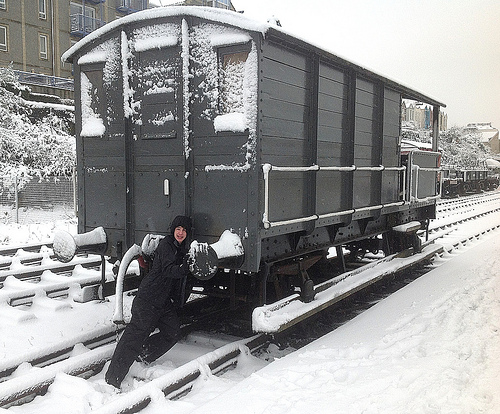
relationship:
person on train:
[81, 208, 202, 395] [65, 14, 441, 276]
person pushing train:
[81, 208, 202, 395] [65, 14, 441, 276]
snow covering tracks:
[21, 374, 97, 413] [9, 324, 229, 413]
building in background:
[1, 1, 147, 105] [1, 84, 78, 106]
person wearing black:
[81, 208, 202, 395] [153, 284, 158, 289]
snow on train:
[167, 5, 275, 34] [65, 14, 441, 276]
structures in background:
[397, 106, 496, 160] [403, 148, 499, 157]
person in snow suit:
[81, 208, 202, 395] [107, 239, 191, 396]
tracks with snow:
[9, 324, 229, 413] [21, 374, 97, 413]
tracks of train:
[9, 324, 229, 413] [65, 14, 441, 276]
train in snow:
[65, 14, 441, 276] [21, 374, 97, 413]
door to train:
[130, 34, 190, 233] [65, 14, 441, 276]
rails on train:
[255, 162, 445, 174] [65, 14, 441, 276]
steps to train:
[392, 215, 429, 236] [65, 14, 441, 276]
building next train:
[1, 1, 147, 105] [65, 14, 441, 276]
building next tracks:
[1, 1, 147, 105] [9, 324, 229, 413]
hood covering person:
[170, 214, 193, 238] [81, 208, 202, 395]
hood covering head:
[170, 214, 193, 238] [169, 211, 193, 250]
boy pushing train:
[81, 208, 202, 395] [65, 14, 441, 276]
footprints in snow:
[362, 300, 498, 406] [222, 247, 497, 411]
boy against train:
[81, 208, 202, 395] [65, 14, 441, 276]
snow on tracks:
[21, 374, 97, 413] [9, 324, 229, 413]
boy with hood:
[81, 208, 202, 395] [171, 214, 191, 233]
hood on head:
[171, 214, 191, 233] [169, 211, 193, 250]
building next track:
[1, 1, 147, 105] [3, 256, 86, 284]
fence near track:
[4, 174, 78, 225] [3, 256, 86, 284]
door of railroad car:
[130, 34, 190, 233] [65, 14, 441, 276]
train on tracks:
[65, 14, 441, 276] [9, 324, 229, 413]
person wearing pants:
[81, 208, 202, 395] [107, 294, 182, 386]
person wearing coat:
[81, 208, 202, 395] [120, 244, 190, 315]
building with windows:
[1, 1, 147, 105] [30, 4, 55, 61]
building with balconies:
[1, 1, 147, 105] [73, 2, 106, 31]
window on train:
[215, 49, 254, 111] [65, 14, 441, 276]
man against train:
[81, 208, 202, 395] [65, 14, 441, 276]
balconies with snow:
[73, 2, 106, 31] [79, 13, 97, 20]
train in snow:
[65, 14, 441, 276] [222, 247, 497, 411]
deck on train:
[389, 94, 439, 203] [65, 14, 441, 276]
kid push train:
[81, 208, 202, 395] [65, 14, 441, 276]